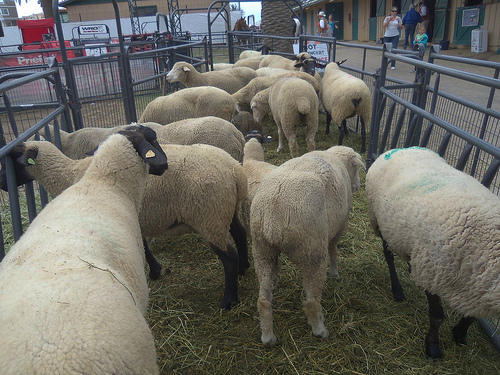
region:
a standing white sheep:
[248, 136, 367, 346]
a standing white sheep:
[359, 139, 498, 362]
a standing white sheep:
[3, 121, 171, 371]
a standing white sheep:
[34, 118, 243, 158]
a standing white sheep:
[246, 76, 321, 153]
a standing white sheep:
[312, 54, 374, 150]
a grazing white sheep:
[130, 84, 240, 124]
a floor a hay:
[125, 119, 477, 372]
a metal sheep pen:
[1, 29, 496, 371]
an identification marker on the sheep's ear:
[134, 139, 167, 168]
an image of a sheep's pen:
[1, 0, 499, 374]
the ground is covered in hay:
[158, 282, 423, 374]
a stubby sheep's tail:
[295, 96, 312, 116]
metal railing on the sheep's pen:
[376, 45, 499, 165]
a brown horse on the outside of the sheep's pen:
[233, 16, 250, 46]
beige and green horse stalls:
[293, 1, 499, 52]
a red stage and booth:
[2, 18, 74, 67]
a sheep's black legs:
[426, 290, 445, 361]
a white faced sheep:
[165, 59, 192, 84]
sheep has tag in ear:
[128, 146, 166, 159]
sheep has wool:
[26, 215, 115, 365]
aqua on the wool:
[378, 141, 495, 206]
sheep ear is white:
[172, 55, 202, 90]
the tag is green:
[12, 153, 54, 189]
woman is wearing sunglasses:
[383, 4, 406, 30]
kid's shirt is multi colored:
[414, 23, 432, 60]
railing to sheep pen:
[386, 77, 458, 144]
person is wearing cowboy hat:
[313, 9, 327, 21]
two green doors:
[346, 6, 377, 46]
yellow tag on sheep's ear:
[143, 148, 153, 159]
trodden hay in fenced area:
[156, 283, 237, 369]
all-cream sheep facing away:
[251, 138, 368, 350]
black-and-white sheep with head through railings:
[1, 132, 256, 309]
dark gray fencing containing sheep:
[374, 43, 498, 181]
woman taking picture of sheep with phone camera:
[380, 5, 403, 70]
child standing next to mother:
[413, 22, 433, 72]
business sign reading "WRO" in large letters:
[78, 23, 109, 36]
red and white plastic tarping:
[14, 14, 77, 69]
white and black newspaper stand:
[470, 24, 487, 56]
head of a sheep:
[115, 122, 170, 184]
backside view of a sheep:
[249, 145, 366, 343]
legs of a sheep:
[425, 289, 478, 362]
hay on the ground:
[167, 342, 418, 373]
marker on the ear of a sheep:
[143, 147, 157, 160]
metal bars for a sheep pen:
[376, 48, 498, 157]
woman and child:
[383, 5, 431, 67]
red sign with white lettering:
[3, 47, 70, 67]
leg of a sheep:
[205, 230, 246, 312]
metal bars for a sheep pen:
[0, 57, 143, 108]